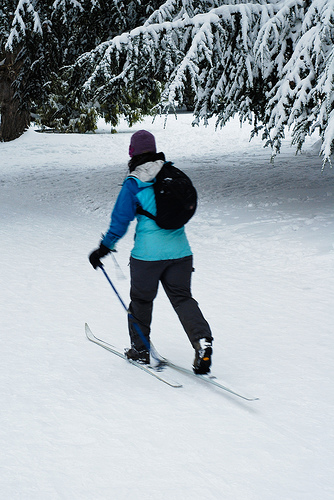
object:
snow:
[273, 11, 320, 93]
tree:
[22, 1, 73, 118]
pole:
[96, 258, 164, 367]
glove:
[88, 244, 110, 270]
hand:
[88, 241, 125, 271]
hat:
[127, 130, 156, 158]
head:
[127, 126, 159, 162]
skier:
[90, 127, 221, 382]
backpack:
[145, 161, 199, 231]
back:
[137, 167, 188, 244]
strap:
[135, 204, 153, 220]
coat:
[106, 166, 194, 263]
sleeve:
[97, 176, 141, 245]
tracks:
[209, 211, 267, 265]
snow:
[38, 149, 86, 232]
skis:
[78, 316, 264, 406]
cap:
[125, 130, 159, 157]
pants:
[126, 253, 208, 349]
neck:
[129, 152, 166, 168]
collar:
[123, 150, 171, 165]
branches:
[129, 7, 332, 111]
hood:
[127, 161, 167, 186]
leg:
[122, 264, 156, 365]